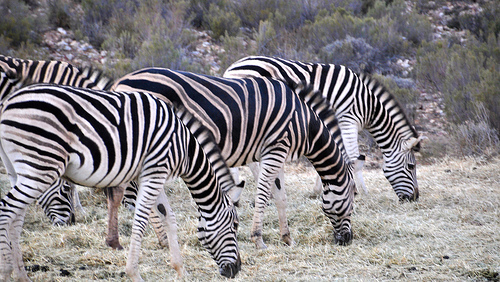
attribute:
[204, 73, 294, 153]
pattern — striped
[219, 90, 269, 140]
fur — zebra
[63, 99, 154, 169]
fur — zebra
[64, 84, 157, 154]
stripes — black, white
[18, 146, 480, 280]
field — grass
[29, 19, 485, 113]
bushes — green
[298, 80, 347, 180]
mane — black, white, zebra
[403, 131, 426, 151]
ear — zebra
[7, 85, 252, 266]
zebra — white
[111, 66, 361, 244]
zebra — white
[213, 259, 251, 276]
nose — black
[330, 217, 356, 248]
nose — black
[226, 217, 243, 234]
eye — black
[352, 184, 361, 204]
eye — black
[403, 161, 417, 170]
eye — black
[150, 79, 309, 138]
stripes — lighter, some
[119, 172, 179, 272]
stripes — faded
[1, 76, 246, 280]
zebra — eating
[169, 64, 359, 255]
zebra — eating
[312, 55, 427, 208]
zebra — eating